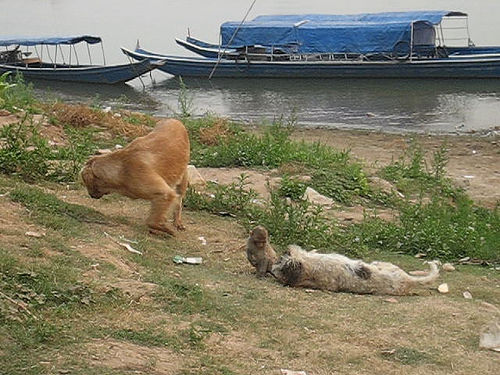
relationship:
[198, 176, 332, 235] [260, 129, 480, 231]
weeds growing in dirt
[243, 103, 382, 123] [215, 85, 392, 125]
ripples in water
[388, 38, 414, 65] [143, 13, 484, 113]
old tire attached to boat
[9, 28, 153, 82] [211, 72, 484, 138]
blue boat on water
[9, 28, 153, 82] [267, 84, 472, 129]
blue boat on water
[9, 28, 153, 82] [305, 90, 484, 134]
blue boat on water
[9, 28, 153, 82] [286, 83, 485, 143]
blue boat on water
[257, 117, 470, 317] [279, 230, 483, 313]
monkey petting dog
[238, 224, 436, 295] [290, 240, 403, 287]
dog with spots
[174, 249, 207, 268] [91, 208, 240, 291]
piece of trash on ground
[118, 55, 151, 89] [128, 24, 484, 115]
large paddle for boat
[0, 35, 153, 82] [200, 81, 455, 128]
blue boat in water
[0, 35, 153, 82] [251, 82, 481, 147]
blue boat in water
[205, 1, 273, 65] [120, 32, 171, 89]
ropes holding anchor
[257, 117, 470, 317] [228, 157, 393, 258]
monkey on ground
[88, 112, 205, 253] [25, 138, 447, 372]
dog on hill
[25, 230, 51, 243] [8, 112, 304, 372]
trash on hill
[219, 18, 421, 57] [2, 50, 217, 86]
cover on boat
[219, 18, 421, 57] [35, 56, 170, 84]
cover covering boat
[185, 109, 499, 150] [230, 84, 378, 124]
sandy shore meets water